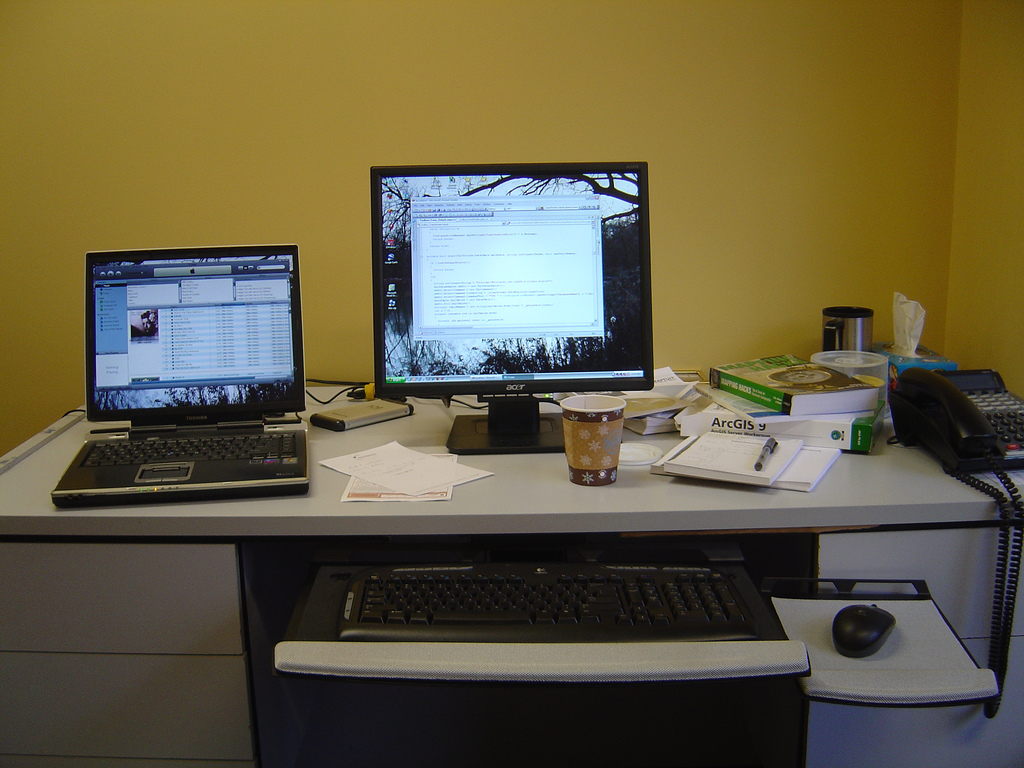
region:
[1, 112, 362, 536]
Laptop sitting on desk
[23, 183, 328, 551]
Laptop sitting on desktop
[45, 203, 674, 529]
Laptop sitting on desk with cup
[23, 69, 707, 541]
Laptop and desktop computer on workstation desk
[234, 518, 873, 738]
Computer keyboard on pullout desk tray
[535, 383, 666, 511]
Coffee cup sitting computer desk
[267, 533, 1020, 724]
Computer keyboard and mouse on tray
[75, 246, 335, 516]
Laptop sitting on desk top.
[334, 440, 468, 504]
Pieces of white paper sitting on desk.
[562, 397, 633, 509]
Brown cup sitting on desk.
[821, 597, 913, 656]
Black computer mouse sitting on desk.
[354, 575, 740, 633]
Black keyboard on desk.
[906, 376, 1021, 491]
Black phone on desk top.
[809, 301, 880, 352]
Black and silver coffee mug on desk.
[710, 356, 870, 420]
Book sitting on desk.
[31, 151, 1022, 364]
Back wall is tannish yellow.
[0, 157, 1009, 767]
Laptop and computer on the desk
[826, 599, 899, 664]
black mouse on the pad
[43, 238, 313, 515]
Black laptop on the desk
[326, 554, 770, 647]
Black keyboard on the desk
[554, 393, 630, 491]
Paper cup on the desk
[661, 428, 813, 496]
Black pen on the notebook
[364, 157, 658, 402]
Black square monitor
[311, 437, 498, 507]
two pieces of paper on the desk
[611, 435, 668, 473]
white plastic lid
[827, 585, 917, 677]
mous is black in color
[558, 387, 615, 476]
cup is yellow and brown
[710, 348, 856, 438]
book is green in color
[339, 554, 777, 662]
keyboard is black in color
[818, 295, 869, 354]
cup is silver in color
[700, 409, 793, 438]
text on book is black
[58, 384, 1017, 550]
Desk is grey in color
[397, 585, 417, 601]
A key on a keyboard.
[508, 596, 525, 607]
A key on a keyboard.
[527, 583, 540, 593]
A key on a keyboard.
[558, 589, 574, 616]
A key on a keyboard.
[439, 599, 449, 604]
A key on a keyboard.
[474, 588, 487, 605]
A key on a keyboard.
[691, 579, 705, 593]
A key on a keyboard.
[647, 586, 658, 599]
A key on a keyboard.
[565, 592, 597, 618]
A key on a keyboard.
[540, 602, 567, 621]
A key on a keyboard.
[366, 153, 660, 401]
large square black screen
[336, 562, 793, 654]
large wide long keyboard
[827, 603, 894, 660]
small round black mouse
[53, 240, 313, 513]
small square black laptop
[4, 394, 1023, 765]
large wide white desk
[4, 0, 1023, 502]
large yellow wide wall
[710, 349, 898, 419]
large square green book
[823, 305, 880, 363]
tall metal round cup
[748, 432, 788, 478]
small long thin pen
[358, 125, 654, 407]
monitor on small desk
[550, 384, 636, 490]
coffee mug on desk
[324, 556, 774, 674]
keyboard on table is black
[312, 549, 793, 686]
keyboard is black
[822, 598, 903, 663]
mouse is black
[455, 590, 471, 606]
A key on a keyboard.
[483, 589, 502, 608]
A key on a keyboard.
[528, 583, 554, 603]
A key on a keyboard.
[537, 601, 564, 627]
A key on a keyboard.